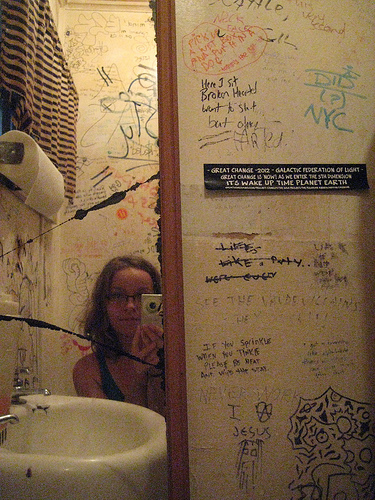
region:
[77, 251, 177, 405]
a girl taking a bathroom selfie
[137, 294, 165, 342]
a small silver camera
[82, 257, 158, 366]
a girl with short hair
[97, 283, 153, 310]
a person wearing glasses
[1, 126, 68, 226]
a roll of white paper towels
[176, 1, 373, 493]
many words written on a wall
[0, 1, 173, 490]
a cracked mirror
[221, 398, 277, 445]
the words i heard jesus written on a wall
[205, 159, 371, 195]
a black sign with white letters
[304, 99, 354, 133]
the letters nyc on the wall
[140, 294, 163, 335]
Silver camera being used in bathroom mirror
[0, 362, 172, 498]
White porcelain bathroom sink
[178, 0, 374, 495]
Things written on the wall of a bathroom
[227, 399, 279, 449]
I heart jesus written on a bathroom wall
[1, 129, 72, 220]
Roll of paper towels reflected in the mirror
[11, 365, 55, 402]
Silver public bathroom faucet on white sink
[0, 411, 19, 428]
Silver public bathroom faucet on white sink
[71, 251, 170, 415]
Girl taking a mirror selfie in a bathroom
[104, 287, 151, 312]
Black rimmed glasses on a girl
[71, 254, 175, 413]
Girl taking a selfie with camera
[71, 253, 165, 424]
Girl in a bathroom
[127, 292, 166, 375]
Hands holding a camera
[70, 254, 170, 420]
Girl taking a picture of herself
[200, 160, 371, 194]
Sticker on bathroom wall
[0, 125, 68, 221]
Paper towels for drying hands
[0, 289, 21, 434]
Soap dispenser to clean hands with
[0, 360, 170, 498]
Sink in a public bathroom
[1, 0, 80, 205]
Striped curtain covering the window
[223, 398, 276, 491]
I heart Jesus graffiti on bathroom wall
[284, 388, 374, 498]
Drawing on bathroom wall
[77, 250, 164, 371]
Woman holding a camera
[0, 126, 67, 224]
Roll of paper towels on wall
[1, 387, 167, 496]
White bathroom sink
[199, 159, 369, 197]
Black sign with white letters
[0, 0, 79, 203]
Black and tan striped curtain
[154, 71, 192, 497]
Wood frame of mirror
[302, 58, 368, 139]
Green writing on white wall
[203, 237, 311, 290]
Black ink on a white wall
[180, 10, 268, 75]
Red ink on a white wall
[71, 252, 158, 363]
Reflection of a girl wearing glasses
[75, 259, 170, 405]
woman takign a selfie in a mirror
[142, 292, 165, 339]
camera in the woman's hands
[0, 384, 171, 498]
sink in the bathroom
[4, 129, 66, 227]
toilet paper above the toilet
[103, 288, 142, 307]
eyeglasses on the woman's face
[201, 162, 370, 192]
black bumper sticker placed on the wall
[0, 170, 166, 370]
cracks in the mirror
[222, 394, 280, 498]
black writing on the wall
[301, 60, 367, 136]
blue writing on the wall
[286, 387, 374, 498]
drawing in black marker on the wall